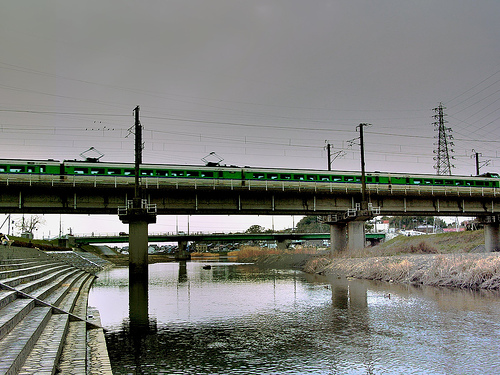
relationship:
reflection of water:
[103, 313, 322, 373] [161, 280, 211, 316]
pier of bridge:
[128, 221, 150, 281] [1, 176, 497, 212]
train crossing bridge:
[0, 158, 500, 188] [3, 173, 495, 267]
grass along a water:
[294, 253, 499, 290] [87, 256, 500, 374]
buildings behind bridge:
[68, 219, 442, 245] [11, 137, 444, 245]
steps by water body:
[0, 246, 115, 373] [87, 252, 499, 372]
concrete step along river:
[87, 307, 101, 324] [112, 268, 499, 373]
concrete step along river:
[87, 327, 113, 375] [112, 268, 499, 373]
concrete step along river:
[46, 269, 90, 301] [112, 268, 499, 373]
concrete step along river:
[59, 286, 79, 310] [112, 268, 499, 373]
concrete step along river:
[0, 298, 37, 337] [112, 268, 499, 373]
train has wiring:
[0, 158, 500, 188] [2, 103, 499, 175]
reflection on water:
[120, 284, 322, 374] [101, 234, 498, 374]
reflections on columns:
[328, 285, 375, 310] [328, 215, 360, 252]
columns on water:
[328, 215, 360, 252] [193, 284, 308, 360]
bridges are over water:
[0, 173, 500, 262] [87, 256, 500, 374]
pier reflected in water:
[8, 151, 493, 230] [186, 270, 383, 351]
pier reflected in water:
[325, 211, 370, 318] [186, 270, 383, 351]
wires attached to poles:
[101, 97, 443, 168] [134, 106, 487, 190]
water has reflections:
[90, 260, 497, 373] [348, 285, 366, 310]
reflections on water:
[348, 285, 366, 310] [90, 260, 497, 373]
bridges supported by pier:
[2, 173, 499, 336] [129, 210, 159, 323]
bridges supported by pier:
[2, 173, 499, 336] [329, 214, 366, 314]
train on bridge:
[3, 166, 493, 206] [1, 151, 498, 262]